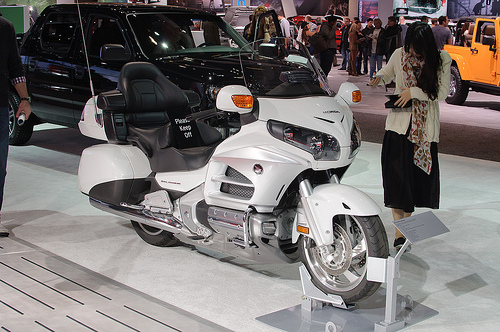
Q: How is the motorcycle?
A: Motionless.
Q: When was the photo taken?
A: Daytime.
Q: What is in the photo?
A: Motorcycle.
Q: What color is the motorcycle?
A: White.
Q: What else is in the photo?
A: Vehicle.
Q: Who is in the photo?
A: A woman.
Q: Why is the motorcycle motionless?
A: It is parked.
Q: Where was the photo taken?
A: At a car show.